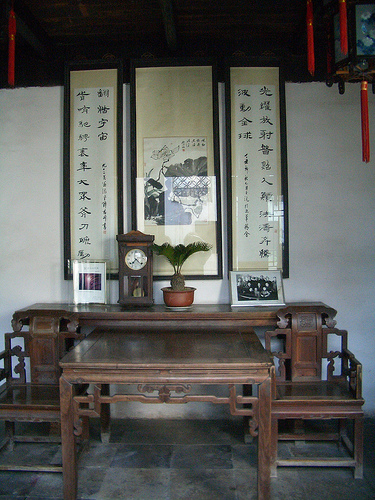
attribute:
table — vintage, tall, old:
[52, 322, 285, 499]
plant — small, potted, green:
[154, 241, 214, 312]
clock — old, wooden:
[115, 227, 157, 310]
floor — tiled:
[0, 393, 374, 494]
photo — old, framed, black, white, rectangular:
[220, 266, 288, 308]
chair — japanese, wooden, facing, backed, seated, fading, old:
[10, 309, 365, 482]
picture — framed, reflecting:
[69, 260, 111, 308]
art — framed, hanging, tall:
[58, 60, 293, 285]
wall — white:
[8, 59, 370, 346]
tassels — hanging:
[5, 6, 373, 172]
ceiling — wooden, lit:
[2, 1, 373, 82]